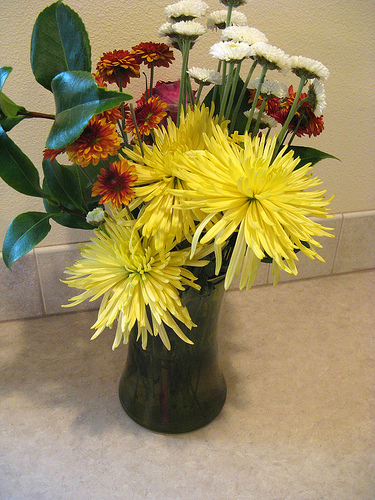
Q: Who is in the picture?
A: No one.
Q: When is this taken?
A: During the day.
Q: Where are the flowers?
A: In a vase.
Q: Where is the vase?
A: On a countertop.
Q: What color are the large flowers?
A: Yellow.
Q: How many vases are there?
A: One.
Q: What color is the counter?
A: White.